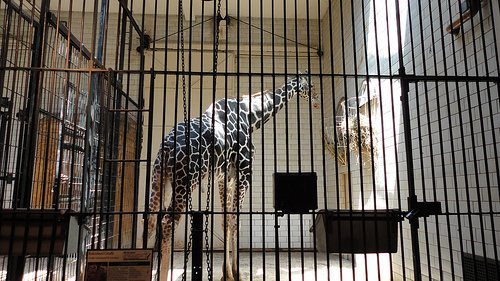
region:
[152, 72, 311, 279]
long girraffee with black spots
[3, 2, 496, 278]
metal black vertical cage with horizontal bars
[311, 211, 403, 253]
black box on the cage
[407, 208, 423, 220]
silver padlock for the cage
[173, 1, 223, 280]
long black chains inside the cage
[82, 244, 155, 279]
a notice with writings on it on the cage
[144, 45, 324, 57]
long white bar in cage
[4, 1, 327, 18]
white large ceiling in cage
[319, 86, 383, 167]
feeding chamber in cage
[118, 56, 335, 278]
This is a giraffe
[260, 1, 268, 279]
This is a metal bar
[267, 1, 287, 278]
This is a metal bar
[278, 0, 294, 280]
This is a metal bar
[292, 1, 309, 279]
This is a metal bar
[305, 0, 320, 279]
This is a metal bar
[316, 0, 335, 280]
This is a metal bar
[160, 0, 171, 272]
This is a metal bar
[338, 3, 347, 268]
This is a metal bar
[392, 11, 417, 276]
This is a metal bar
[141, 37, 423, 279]
view at a girrafe zoo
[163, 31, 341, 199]
the girrafe is tall in height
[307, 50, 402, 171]
stuffs are on the wall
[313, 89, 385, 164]
the sack is brown in color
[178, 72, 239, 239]
the chains are hang from the wall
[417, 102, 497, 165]
walls are white in color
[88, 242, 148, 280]
the poster is white in color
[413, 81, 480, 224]
the fnce is made of metals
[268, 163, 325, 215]
the locking box is black in color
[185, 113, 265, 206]
the giraffe is brown and white in color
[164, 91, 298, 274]
A black and brown giraffe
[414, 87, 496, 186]
A Black mesh cage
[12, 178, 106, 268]
A Black mesh cage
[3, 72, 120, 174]
A Black mesh cage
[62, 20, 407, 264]
a giraffe in a cage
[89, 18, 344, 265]
a giraffe that is inside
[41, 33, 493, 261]
a giraffe in a cage inside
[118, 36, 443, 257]
a giraffe in a large cage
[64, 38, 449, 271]
a large giraffe in an inside cage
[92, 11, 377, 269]
a metal cage around a giraffe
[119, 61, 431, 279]
a giraffe standing in a cage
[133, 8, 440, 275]
a giraffe standing inside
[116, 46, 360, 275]
a giraffe with a long neck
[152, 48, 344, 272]
a long neck giraffe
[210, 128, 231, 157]
a spot on the giraffe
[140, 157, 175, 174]
a spot on the giraffe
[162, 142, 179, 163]
a spot on the giraffe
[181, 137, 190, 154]
a spot on the giraffe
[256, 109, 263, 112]
a spot on the giraffe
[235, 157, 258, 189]
a spot on the giraffe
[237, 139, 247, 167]
a spot on the giraffe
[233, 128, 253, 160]
a spot on the giraffe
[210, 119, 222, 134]
a spot on the giraffe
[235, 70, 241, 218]
A thin metal bar.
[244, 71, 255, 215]
A thin metal bar.